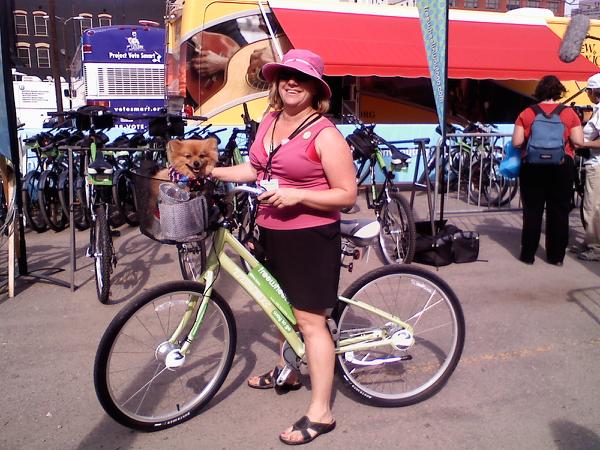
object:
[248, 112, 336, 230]
shirt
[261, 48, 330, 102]
hat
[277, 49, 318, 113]
head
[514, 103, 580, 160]
shirt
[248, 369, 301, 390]
sandal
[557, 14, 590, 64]
sound boom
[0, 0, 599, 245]
background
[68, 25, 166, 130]
bus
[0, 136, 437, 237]
bike rack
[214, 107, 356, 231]
top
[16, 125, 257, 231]
row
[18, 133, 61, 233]
bike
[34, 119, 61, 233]
bike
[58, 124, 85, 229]
bike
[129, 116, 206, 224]
bike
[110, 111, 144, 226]
bike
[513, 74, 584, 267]
lady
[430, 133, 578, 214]
barrier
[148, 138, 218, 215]
dog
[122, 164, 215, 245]
basket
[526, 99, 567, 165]
back pack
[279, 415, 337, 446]
sandal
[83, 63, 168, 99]
grate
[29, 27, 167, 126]
back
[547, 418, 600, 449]
shadow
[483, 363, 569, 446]
ground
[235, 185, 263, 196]
tag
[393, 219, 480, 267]
luggage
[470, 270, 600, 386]
ground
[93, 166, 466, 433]
bicycle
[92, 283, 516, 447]
spot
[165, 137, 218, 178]
head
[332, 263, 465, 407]
wheel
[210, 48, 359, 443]
lady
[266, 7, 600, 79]
awning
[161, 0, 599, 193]
truck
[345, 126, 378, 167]
bag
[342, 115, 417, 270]
bike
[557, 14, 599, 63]
mic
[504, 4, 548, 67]
air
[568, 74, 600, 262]
person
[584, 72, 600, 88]
hat